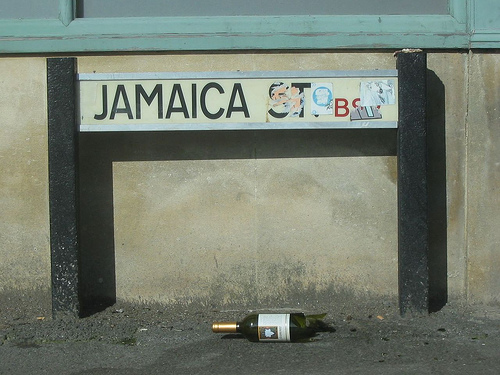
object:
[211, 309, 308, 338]
wine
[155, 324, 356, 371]
shadow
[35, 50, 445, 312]
street board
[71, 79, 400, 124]
writing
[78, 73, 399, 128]
board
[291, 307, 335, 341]
glass shard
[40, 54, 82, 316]
post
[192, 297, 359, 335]
bottle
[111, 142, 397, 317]
grey wall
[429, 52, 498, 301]
grey wall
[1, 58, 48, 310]
grey wall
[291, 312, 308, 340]
bottom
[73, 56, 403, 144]
sign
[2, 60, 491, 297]
wall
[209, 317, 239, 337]
cap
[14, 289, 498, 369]
street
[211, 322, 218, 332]
lid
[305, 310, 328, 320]
piece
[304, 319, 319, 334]
piece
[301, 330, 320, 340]
piece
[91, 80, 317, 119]
jamaica st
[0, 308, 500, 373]
ground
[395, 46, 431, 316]
post